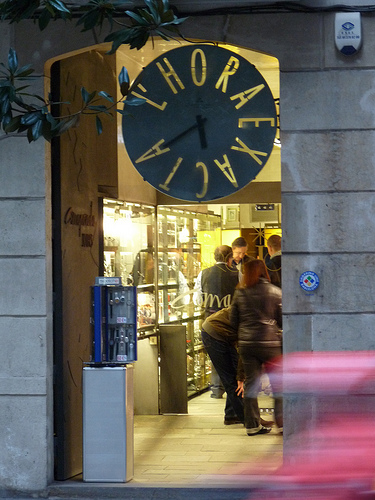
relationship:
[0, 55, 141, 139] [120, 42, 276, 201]
leaves next to clock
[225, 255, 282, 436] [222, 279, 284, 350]
girl wearing jacket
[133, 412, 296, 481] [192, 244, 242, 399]
ground below man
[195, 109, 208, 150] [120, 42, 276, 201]
hands on clock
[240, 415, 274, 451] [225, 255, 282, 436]
shoe on girl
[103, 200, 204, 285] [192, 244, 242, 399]
glass next to man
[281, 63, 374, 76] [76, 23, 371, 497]
line on building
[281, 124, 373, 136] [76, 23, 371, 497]
line on building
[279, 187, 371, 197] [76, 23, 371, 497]
line on building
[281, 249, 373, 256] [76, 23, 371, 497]
line on building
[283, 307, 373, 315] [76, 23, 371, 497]
line on building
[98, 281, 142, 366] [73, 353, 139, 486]
watches on stand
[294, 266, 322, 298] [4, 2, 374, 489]
sign on side of building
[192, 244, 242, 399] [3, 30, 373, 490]
man inside store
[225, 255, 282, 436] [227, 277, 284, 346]
girl wearing jacket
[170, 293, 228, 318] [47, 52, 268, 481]
writing on window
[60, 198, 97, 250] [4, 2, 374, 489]
sign on side of building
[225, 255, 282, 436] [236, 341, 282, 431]
girl wearing pants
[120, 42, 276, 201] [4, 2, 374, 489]
clock on building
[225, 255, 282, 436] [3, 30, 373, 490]
girl in store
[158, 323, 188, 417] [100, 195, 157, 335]
door on display case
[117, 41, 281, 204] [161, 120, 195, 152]
clock on hand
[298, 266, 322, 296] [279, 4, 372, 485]
sign on wall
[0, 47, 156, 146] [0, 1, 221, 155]
leaves on tree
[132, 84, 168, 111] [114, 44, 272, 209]
letters on sign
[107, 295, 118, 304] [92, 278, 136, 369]
watch in case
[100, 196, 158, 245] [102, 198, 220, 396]
lights on display cases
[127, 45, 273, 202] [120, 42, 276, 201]
word on clock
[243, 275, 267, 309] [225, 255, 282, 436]
hair on girl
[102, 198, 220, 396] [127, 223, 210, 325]
display cases with items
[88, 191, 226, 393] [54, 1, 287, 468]
display in store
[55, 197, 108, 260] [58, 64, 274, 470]
sign for store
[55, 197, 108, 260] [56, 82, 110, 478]
sign on door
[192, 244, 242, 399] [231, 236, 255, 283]
man talking to man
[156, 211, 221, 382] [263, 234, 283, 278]
glass next to person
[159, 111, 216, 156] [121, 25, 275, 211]
hands on clock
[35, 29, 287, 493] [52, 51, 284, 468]
entry into store